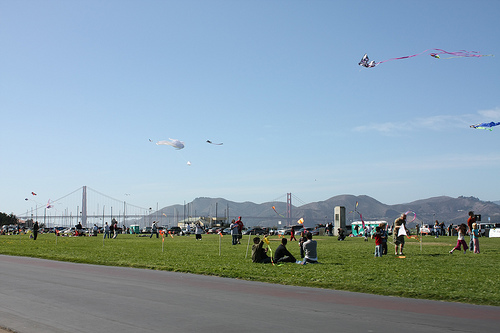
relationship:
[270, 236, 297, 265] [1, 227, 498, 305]
person sitting in grass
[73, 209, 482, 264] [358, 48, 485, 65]
people in a park flying kite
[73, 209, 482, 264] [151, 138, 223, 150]
people in a park flying kite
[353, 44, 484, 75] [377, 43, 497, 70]
kite with pink tails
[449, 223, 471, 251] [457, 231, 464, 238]
girl wears white top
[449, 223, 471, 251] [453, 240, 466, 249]
girl wears burgundy capris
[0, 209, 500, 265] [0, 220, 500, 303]
people sitting on grass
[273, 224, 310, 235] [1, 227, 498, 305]
vehicle on grass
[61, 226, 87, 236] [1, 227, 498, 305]
vehicle on grass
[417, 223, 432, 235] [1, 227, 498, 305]
vehicle on grass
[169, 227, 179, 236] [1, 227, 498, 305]
vehicle on grass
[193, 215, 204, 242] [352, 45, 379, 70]
person flies kite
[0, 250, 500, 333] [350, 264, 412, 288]
road next to field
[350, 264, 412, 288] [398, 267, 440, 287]
field has grass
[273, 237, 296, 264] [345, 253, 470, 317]
person sits on grass